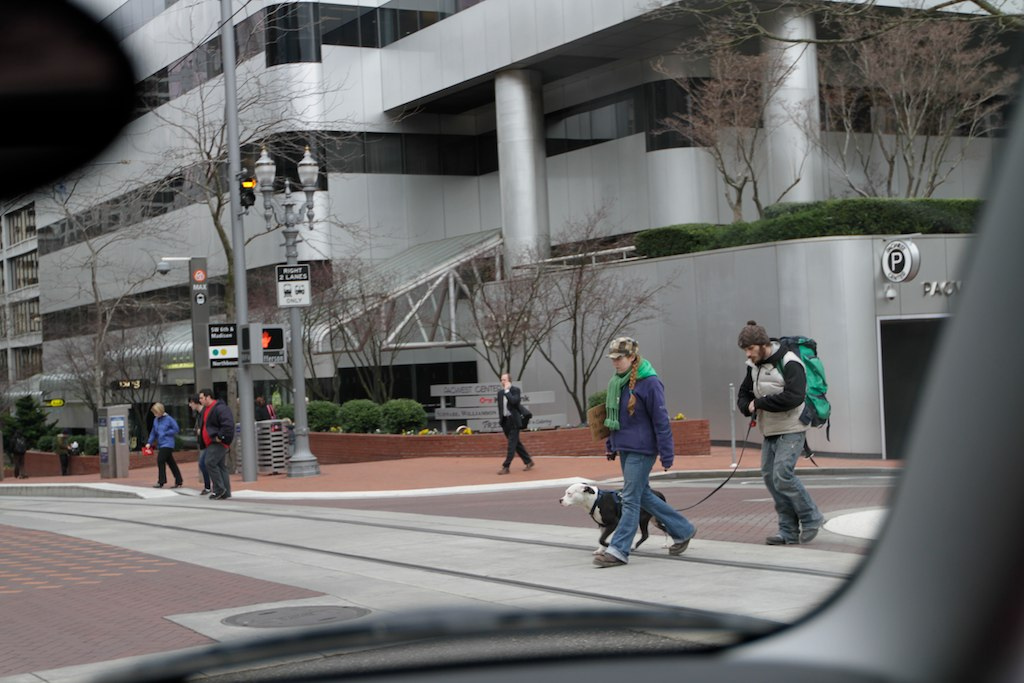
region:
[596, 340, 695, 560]
a woman is walking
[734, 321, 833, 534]
a man is walking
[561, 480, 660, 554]
a dog is walking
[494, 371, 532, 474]
a person is walking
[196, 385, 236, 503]
a man is standing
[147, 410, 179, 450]
the jacket is blue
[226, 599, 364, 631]
sewer lid is metal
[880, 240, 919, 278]
sign on the wall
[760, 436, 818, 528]
the pants are blue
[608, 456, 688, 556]
the pants are blue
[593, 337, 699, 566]
woman wearing a green scarf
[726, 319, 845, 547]
man wearing a green backpack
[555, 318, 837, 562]
white man walking a dog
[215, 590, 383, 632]
a steel manhole cover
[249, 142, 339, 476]
a street lamp post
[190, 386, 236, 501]
man wearing a red shirt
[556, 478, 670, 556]
a dog with a white face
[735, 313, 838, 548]
guy wearing a winter hat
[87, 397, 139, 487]
a street parking meter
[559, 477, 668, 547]
dog is black and white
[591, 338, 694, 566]
girl with a braid has a green scarf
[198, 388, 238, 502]
man is wearing a red t-shirt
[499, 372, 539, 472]
man in a suit is talking on his phone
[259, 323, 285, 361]
red hand is shown on the pedestrian sign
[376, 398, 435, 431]
small, round bush in a planter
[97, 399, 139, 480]
a vending machine to pay for services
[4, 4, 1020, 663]
The windshield of the car through which this picture is taken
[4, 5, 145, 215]
Rear view mirror in front of the driver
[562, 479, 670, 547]
A dog being walked with a leash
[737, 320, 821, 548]
man holding the leash of the dog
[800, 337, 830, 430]
A green and black backpack on the man's shoulders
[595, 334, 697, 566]
A man crossing the road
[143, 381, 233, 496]
A few people waiting at the corner to cross the road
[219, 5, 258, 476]
A tall street light pole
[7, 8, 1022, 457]
A gray building on the far side of the road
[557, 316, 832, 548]
man walking a dog on a leash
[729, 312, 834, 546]
man wearing large green backpack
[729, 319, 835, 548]
man wearing poofy white and black coat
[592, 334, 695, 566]
woman with braids wearing green scarf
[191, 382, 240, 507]
man walking wearing red shirt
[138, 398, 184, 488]
woman holding red object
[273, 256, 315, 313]
black and white traffic sign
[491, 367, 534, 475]
man in black suit talking on his cellphone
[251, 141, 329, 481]
double lamp street light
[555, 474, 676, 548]
black and white dog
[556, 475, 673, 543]
Dog on a leash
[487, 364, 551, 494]
Person on a phone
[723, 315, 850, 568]
Man walking a dog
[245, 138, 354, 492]
Lightpost made of metal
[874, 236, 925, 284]
Sign on a building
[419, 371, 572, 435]
Sign in front of a building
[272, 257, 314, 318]
Sign on a post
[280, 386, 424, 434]
Bushes in a row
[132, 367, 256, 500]
People crossing the road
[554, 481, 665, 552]
a large black and white dog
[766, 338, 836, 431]
a large green and black backpack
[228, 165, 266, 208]
a black traffic light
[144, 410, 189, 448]
a woman's blue coat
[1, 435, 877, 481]
a paved sidewalk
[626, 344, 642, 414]
a woman's long brown braided hair